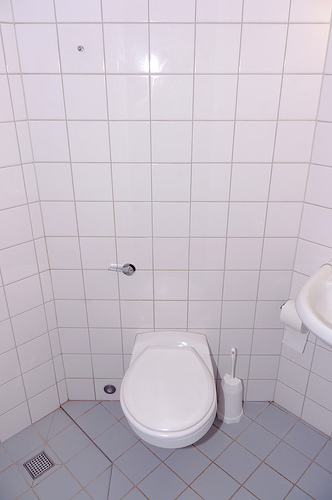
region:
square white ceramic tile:
[147, 72, 193, 121]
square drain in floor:
[20, 451, 50, 480]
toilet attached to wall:
[120, 326, 219, 449]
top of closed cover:
[121, 343, 213, 433]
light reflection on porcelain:
[175, 339, 193, 352]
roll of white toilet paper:
[277, 296, 308, 351]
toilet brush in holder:
[217, 346, 243, 423]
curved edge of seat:
[293, 265, 329, 341]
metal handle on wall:
[106, 261, 136, 276]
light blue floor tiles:
[2, 397, 330, 498]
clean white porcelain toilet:
[116, 330, 218, 451]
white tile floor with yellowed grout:
[0, 400, 331, 498]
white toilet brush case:
[214, 344, 245, 424]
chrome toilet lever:
[103, 263, 137, 276]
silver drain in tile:
[24, 449, 57, 482]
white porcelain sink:
[291, 258, 330, 353]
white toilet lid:
[120, 341, 214, 432]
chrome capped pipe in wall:
[102, 383, 115, 394]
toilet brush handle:
[229, 344, 238, 376]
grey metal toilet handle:
[110, 264, 133, 275]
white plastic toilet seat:
[123, 345, 215, 431]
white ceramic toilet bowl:
[117, 332, 218, 450]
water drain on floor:
[22, 452, 53, 480]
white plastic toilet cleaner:
[220, 347, 243, 423]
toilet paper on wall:
[280, 300, 308, 353]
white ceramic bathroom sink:
[296, 262, 331, 343]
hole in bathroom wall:
[76, 44, 83, 52]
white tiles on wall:
[2, 1, 331, 445]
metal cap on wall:
[103, 384, 114, 394]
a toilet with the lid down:
[115, 317, 221, 454]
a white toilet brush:
[214, 342, 250, 428]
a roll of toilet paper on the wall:
[273, 295, 316, 354]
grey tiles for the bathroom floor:
[2, 396, 327, 498]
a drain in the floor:
[15, 448, 63, 483]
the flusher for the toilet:
[103, 255, 142, 280]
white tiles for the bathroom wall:
[3, 6, 331, 438]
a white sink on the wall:
[293, 253, 331, 345]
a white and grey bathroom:
[0, 196, 331, 486]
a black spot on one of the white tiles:
[55, 33, 102, 66]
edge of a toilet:
[152, 429, 175, 453]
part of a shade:
[214, 391, 235, 424]